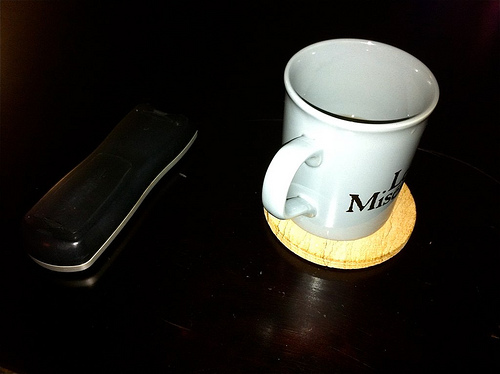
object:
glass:
[261, 38, 439, 240]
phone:
[18, 108, 199, 273]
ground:
[340, 66, 419, 130]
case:
[22, 107, 198, 272]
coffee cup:
[261, 38, 440, 241]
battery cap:
[26, 152, 133, 242]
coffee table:
[1, 0, 499, 372]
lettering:
[389, 169, 402, 191]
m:
[346, 192, 380, 212]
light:
[287, 273, 341, 330]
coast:
[263, 181, 417, 269]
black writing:
[383, 193, 392, 206]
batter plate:
[27, 153, 136, 239]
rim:
[282, 38, 439, 132]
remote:
[22, 105, 198, 272]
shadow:
[293, 93, 415, 123]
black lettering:
[376, 191, 387, 209]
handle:
[262, 136, 323, 220]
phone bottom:
[20, 106, 197, 265]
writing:
[393, 188, 400, 200]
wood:
[240, 305, 492, 365]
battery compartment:
[28, 152, 134, 239]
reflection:
[268, 270, 342, 360]